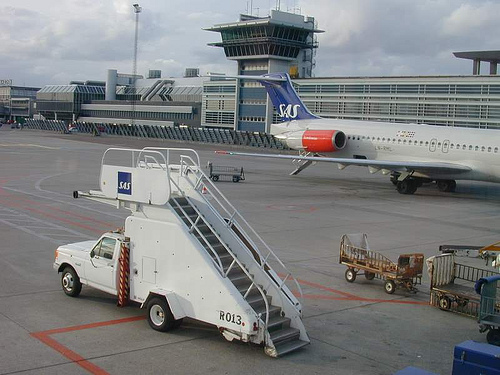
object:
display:
[279, 103, 301, 118]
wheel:
[438, 178, 458, 193]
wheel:
[395, 179, 418, 195]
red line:
[30, 313, 156, 374]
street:
[0, 123, 497, 373]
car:
[52, 147, 311, 359]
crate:
[258, 72, 322, 124]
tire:
[145, 296, 182, 331]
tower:
[202, 0, 326, 89]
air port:
[0, 74, 499, 374]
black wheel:
[437, 296, 451, 311]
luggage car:
[427, 253, 500, 313]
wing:
[213, 150, 472, 173]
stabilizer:
[196, 72, 324, 121]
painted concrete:
[297, 280, 431, 305]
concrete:
[16, 319, 157, 375]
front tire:
[62, 266, 82, 297]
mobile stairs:
[72, 146, 310, 359]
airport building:
[0, 0, 498, 150]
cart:
[338, 233, 423, 294]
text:
[118, 182, 130, 191]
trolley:
[338, 232, 498, 346]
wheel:
[383, 280, 397, 294]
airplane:
[198, 70, 499, 195]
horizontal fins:
[213, 73, 298, 91]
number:
[220, 311, 242, 325]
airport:
[0, 7, 483, 208]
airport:
[52, 4, 483, 298]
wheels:
[60, 266, 182, 332]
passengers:
[341, 131, 500, 159]